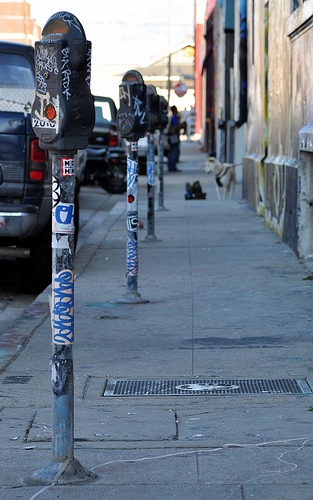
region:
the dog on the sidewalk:
[203, 156, 234, 200]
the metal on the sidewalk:
[103, 375, 312, 397]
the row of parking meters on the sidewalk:
[29, 10, 168, 483]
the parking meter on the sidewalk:
[115, 69, 147, 302]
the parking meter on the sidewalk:
[29, 11, 94, 484]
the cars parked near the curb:
[0, 40, 148, 297]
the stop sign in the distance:
[174, 83, 186, 95]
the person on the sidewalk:
[167, 104, 187, 171]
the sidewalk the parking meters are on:
[0, 140, 312, 499]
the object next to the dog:
[182, 180, 205, 199]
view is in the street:
[24, 54, 305, 323]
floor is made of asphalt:
[200, 441, 260, 499]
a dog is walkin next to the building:
[196, 142, 272, 200]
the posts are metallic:
[52, 284, 80, 440]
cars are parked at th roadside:
[98, 89, 136, 188]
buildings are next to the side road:
[244, 74, 311, 169]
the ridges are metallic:
[133, 374, 304, 409]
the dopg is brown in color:
[200, 148, 255, 209]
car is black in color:
[92, 89, 130, 158]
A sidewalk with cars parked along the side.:
[0, 1, 312, 499]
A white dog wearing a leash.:
[203, 156, 243, 201]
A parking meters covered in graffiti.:
[24, 10, 171, 484]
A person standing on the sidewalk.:
[165, 106, 188, 175]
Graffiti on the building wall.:
[246, 0, 311, 232]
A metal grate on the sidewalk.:
[103, 375, 310, 396]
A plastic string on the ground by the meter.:
[18, 433, 310, 498]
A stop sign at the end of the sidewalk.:
[172, 81, 187, 97]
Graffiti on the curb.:
[0, 301, 50, 403]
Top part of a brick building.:
[0, 0, 40, 48]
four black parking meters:
[25, 4, 174, 159]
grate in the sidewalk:
[103, 372, 300, 396]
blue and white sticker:
[50, 201, 74, 234]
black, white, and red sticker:
[63, 157, 74, 174]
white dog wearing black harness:
[202, 157, 238, 196]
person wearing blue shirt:
[164, 104, 185, 171]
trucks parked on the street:
[2, 40, 131, 283]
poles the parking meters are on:
[50, 131, 169, 463]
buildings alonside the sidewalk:
[196, 1, 312, 243]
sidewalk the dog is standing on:
[10, 112, 308, 498]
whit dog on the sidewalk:
[203, 154, 238, 201]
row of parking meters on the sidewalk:
[33, 9, 174, 486]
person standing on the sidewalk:
[164, 102, 189, 178]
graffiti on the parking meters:
[35, 33, 174, 480]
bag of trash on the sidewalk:
[99, 160, 128, 189]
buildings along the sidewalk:
[198, 0, 312, 274]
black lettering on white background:
[60, 155, 76, 177]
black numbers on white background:
[30, 117, 53, 126]